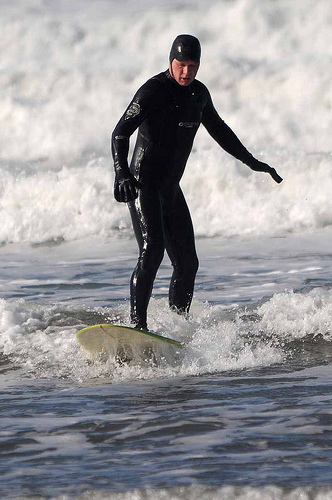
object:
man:
[110, 32, 284, 328]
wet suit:
[110, 75, 284, 331]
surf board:
[73, 322, 199, 372]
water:
[2, 350, 330, 496]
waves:
[3, 299, 331, 378]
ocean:
[5, 7, 327, 495]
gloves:
[239, 154, 288, 188]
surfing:
[71, 32, 287, 376]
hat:
[168, 32, 206, 65]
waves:
[8, 23, 332, 238]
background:
[3, 10, 332, 131]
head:
[167, 32, 203, 91]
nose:
[181, 67, 191, 78]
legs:
[126, 176, 170, 339]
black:
[160, 100, 179, 180]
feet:
[126, 319, 153, 339]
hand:
[244, 160, 299, 190]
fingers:
[270, 165, 286, 188]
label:
[112, 154, 126, 178]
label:
[171, 41, 192, 57]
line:
[93, 324, 121, 347]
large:
[10, 17, 330, 218]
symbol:
[119, 96, 145, 121]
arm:
[108, 77, 162, 174]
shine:
[127, 184, 155, 266]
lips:
[180, 74, 193, 86]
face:
[172, 53, 201, 87]